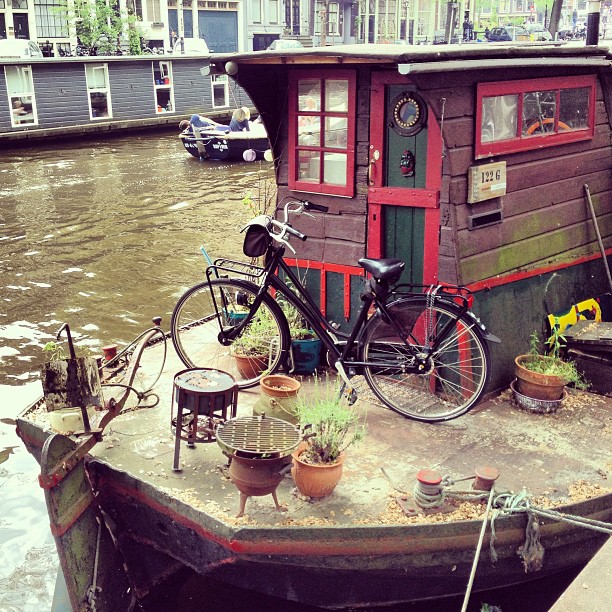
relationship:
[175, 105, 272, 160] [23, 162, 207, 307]
boat in water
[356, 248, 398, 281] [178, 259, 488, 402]
seat on bike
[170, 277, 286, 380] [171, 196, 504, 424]
tire on bicycle